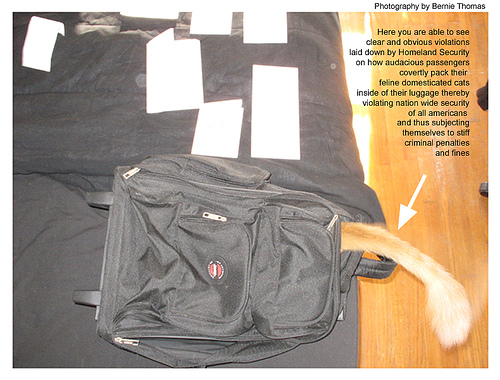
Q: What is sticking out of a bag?
A: Cat's tail.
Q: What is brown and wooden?
A: Floor.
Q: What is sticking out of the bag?
A: A tail.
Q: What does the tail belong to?
A: An animal.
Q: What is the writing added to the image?
A: Black text.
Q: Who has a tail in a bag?
A: An animal.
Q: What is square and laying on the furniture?
A: Paper.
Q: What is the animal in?
A: Suitcase.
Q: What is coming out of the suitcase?
A: Tail.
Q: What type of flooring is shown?
A: Wooden.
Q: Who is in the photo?
A: No body.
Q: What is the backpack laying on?
A: Bed.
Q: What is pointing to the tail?
A: Arrow.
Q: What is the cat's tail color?
A: Orange.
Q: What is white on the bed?
A: Paper.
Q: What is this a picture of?
A: Backpack.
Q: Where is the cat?
A: Inside backpack.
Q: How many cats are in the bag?
A: One.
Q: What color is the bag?
A: Black.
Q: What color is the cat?
A: Orange.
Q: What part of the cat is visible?
A: Tail.